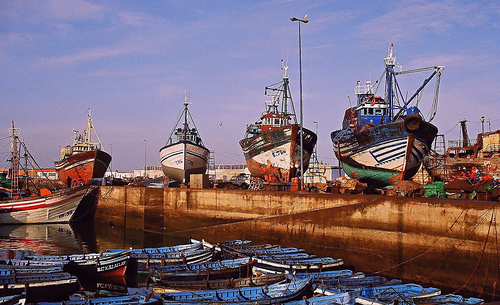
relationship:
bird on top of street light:
[276, 10, 322, 30] [277, 9, 322, 33]